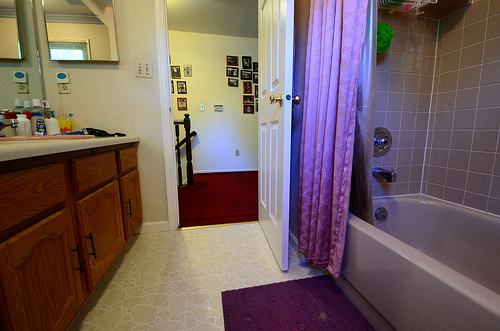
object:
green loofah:
[376, 20, 393, 55]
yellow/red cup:
[58, 119, 73, 133]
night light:
[56, 71, 70, 84]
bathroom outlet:
[54, 71, 70, 94]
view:
[0, 0, 500, 331]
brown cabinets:
[0, 145, 143, 323]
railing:
[172, 113, 198, 188]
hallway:
[168, 0, 258, 229]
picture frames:
[225, 54, 259, 115]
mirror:
[45, 0, 120, 64]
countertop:
[0, 134, 141, 163]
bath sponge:
[369, 21, 395, 55]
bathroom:
[0, 0, 500, 331]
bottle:
[30, 111, 47, 135]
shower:
[315, 0, 480, 313]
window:
[16, 41, 91, 61]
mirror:
[0, 0, 120, 62]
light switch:
[133, 59, 154, 78]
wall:
[110, 2, 170, 222]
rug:
[221, 271, 389, 330]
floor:
[61, 216, 375, 331]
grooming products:
[0, 93, 76, 140]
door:
[246, 0, 302, 272]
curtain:
[294, 0, 364, 281]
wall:
[169, 26, 264, 181]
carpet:
[177, 169, 262, 230]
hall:
[162, 0, 269, 224]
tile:
[365, 0, 500, 216]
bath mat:
[218, 272, 375, 330]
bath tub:
[330, 178, 500, 331]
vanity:
[10, 147, 143, 323]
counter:
[1, 96, 141, 161]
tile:
[87, 218, 316, 328]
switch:
[132, 57, 155, 79]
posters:
[221, 55, 240, 89]